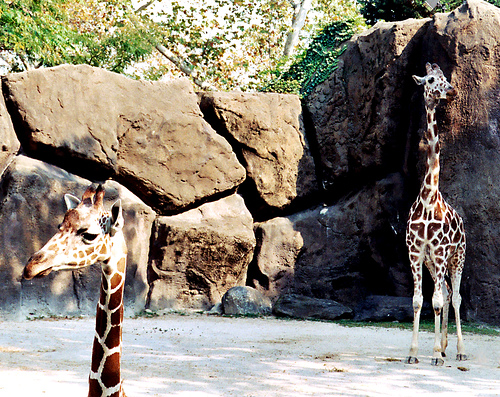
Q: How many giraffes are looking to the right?
A: 1.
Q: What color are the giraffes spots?
A: Brown.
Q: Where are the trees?
A: Behind the boulders.